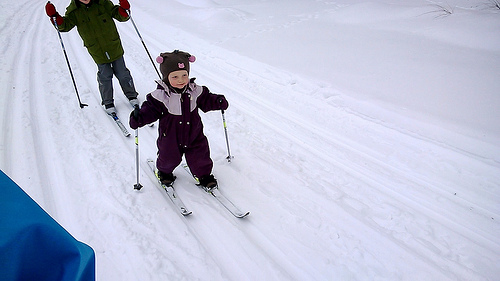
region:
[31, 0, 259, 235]
two kids on skis, one a toddler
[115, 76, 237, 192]
toddler wears royal purple skiing suit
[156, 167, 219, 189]
toddler has tiny royal purple shoes beneath black ski straps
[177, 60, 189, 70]
toddler has animal motif of some kind @ centre of toddler's tiny skiing hat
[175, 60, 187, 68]
animal motif is pink & has pointy ears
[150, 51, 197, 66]
hat is kinda sorta jesterish & has two pink pompoms on either side which match animal motif @ front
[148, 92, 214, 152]
toddler ski suit is closed w/ silvertone snaps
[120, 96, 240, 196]
little bits of yellow tape around tiny toddler's tiny ski poles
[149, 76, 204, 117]
yoke of toddler's ski suit is lavender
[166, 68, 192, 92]
toddler wears smile, has chubby red cheeks from the cold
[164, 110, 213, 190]
Person wearing purple snow suit.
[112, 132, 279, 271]
Little white skis on kid's feet.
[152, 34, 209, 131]
Kid is wearing gray and pink hat.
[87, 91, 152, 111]
Person wearing gray pants.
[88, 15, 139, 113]
Person wearing green coat.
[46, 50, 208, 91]
Person holding 2 poles.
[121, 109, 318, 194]
Person holding 2 poles.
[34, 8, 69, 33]
Person wearing red gloves.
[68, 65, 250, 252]
2 people skiing.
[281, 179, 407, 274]
Ground is covered in snow.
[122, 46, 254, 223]
baby wearing some skis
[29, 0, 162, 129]
person wearing some skis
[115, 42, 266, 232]
baby wearing a hat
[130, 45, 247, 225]
baby wearing a black jacket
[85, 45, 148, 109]
pair of blue jeans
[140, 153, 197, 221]
baby sized white ski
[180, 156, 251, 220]
baby sized white ski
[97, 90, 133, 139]
long ski with snow on it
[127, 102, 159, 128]
long ski with snow on it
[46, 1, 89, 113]
long black ski pole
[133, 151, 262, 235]
a pair of white skis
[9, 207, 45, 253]
a bright blue fabric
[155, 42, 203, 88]
a brown and pink hat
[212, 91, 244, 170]
a child's ski pole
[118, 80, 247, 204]
a purple ski suit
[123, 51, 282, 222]
a small girl on skis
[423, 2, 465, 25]
a branch in the snow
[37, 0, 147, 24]
a pair of red gloves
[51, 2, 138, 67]
a green ski jacket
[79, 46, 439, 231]
some tracks in the snow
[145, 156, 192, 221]
white childs snow ski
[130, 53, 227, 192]
child wearing snow suit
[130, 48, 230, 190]
child standing on skis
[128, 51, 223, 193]
child skiing on hill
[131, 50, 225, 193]
child skiing in snow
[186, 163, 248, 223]
long white ski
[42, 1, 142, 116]
person wearing green jacket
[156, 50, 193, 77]
brown and pink winter hat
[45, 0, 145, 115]
person skiing on snow hill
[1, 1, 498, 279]
blanket of snow on hill